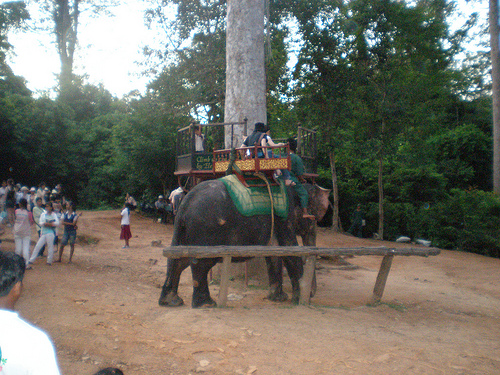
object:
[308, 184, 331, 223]
ear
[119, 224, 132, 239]
skirt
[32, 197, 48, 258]
person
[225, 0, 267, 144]
trunk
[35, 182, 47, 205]
person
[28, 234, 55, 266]
pants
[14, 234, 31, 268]
pants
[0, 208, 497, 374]
brown dirt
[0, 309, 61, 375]
shirt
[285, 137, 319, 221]
person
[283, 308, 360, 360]
ground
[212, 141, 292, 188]
saddle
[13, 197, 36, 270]
people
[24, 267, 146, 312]
pink areas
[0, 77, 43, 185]
trees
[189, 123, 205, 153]
people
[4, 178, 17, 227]
standingpeople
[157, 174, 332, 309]
elephant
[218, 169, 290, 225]
blanket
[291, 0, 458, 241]
tree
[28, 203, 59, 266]
people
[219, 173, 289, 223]
pad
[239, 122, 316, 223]
3 people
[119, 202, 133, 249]
person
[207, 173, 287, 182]
top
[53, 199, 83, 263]
girl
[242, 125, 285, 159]
people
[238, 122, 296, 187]
people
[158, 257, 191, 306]
post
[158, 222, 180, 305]
tail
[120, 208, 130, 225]
shirt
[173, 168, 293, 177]
deck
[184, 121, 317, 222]
they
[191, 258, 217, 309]
hind leg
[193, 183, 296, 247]
body